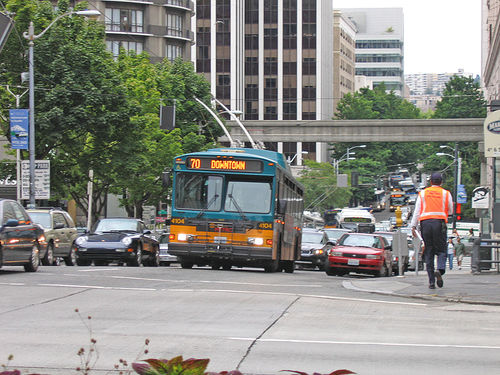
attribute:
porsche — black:
[62, 207, 171, 276]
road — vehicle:
[3, 264, 499, 372]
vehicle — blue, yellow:
[167, 142, 309, 275]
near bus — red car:
[169, 147, 407, 231]